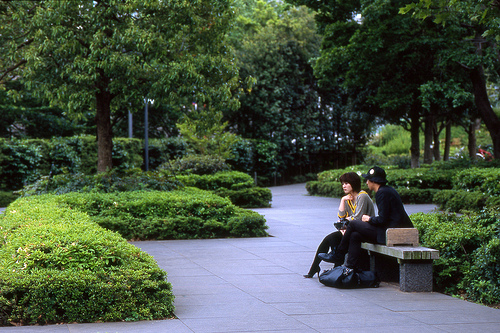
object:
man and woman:
[305, 167, 420, 278]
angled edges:
[141, 252, 170, 288]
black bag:
[319, 266, 381, 289]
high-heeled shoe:
[303, 267, 321, 278]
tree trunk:
[96, 100, 111, 174]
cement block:
[267, 300, 394, 315]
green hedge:
[181, 188, 270, 208]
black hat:
[362, 166, 388, 182]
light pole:
[144, 98, 148, 169]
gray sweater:
[338, 190, 375, 219]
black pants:
[310, 227, 342, 271]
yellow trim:
[348, 200, 357, 213]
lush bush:
[4, 136, 74, 183]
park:
[0, 0, 499, 333]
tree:
[68, 5, 139, 172]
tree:
[314, 19, 420, 169]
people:
[303, 167, 414, 277]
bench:
[360, 243, 440, 292]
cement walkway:
[188, 177, 390, 330]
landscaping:
[0, 0, 499, 333]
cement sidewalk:
[123, 240, 498, 330]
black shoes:
[303, 266, 321, 277]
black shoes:
[318, 250, 344, 264]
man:
[366, 166, 413, 244]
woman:
[304, 172, 374, 278]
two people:
[303, 166, 413, 278]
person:
[361, 166, 413, 270]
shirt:
[376, 187, 414, 229]